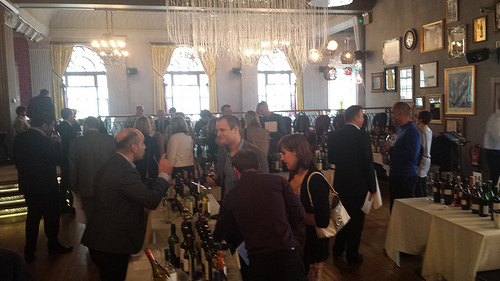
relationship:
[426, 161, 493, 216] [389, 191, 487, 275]
bottle on table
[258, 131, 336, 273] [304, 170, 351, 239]
woman with bag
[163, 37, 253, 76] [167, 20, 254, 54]
light from ceiling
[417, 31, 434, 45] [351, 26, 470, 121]
picture on wall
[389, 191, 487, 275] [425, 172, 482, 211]
table with wine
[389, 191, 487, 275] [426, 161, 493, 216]
table with bottle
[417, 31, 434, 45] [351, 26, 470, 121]
picture with wall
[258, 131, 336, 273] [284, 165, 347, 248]
woman with bag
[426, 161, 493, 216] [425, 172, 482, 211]
bottle of wine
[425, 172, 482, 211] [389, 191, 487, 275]
wine on table